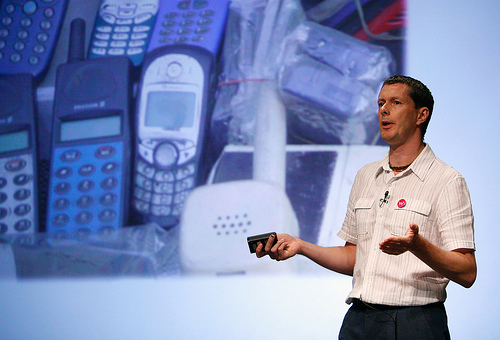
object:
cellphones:
[0, 0, 68, 82]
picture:
[0, 1, 406, 279]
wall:
[0, 0, 497, 339]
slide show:
[0, 0, 406, 283]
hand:
[249, 231, 302, 261]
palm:
[380, 229, 411, 241]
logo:
[395, 198, 408, 208]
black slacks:
[336, 296, 452, 339]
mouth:
[377, 118, 394, 129]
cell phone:
[88, 0, 158, 74]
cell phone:
[143, 0, 230, 56]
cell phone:
[47, 17, 137, 247]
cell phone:
[0, 69, 37, 255]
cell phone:
[129, 41, 214, 232]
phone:
[242, 231, 277, 256]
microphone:
[375, 187, 391, 209]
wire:
[357, 292, 398, 340]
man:
[252, 74, 477, 339]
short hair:
[377, 73, 434, 144]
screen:
[0, 0, 405, 280]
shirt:
[334, 142, 477, 309]